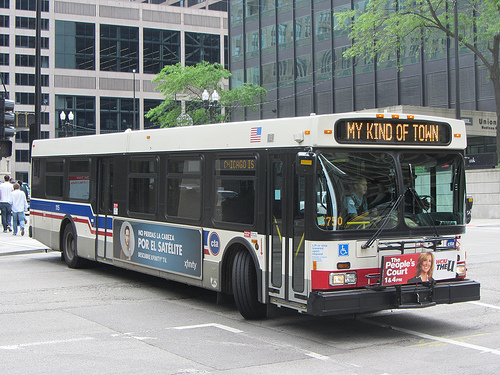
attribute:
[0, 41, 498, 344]
bus — large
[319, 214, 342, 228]
number — lit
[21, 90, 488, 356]
bus — white, long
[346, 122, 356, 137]
letter — orange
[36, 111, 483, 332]
bus — large, turning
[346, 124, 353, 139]
letter — orange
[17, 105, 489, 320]
bus — large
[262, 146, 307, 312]
doors — closed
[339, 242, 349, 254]
sign — blue, white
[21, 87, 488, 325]
bus — large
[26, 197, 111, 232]
stripe — blue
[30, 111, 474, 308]
bus — large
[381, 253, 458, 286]
sign — red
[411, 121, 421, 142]
letter — orange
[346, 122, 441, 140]
letter — orange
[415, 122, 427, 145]
letter — orange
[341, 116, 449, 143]
text — yellow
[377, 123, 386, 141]
letter — orange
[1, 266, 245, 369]
ground — grey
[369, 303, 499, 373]
line — white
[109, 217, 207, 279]
sign — blue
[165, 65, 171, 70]
leaf — green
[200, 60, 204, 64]
leaf — green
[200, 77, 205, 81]
leaf — green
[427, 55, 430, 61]
leaf — green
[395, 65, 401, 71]
leaf — green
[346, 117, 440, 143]
sign — black, orange, lit up